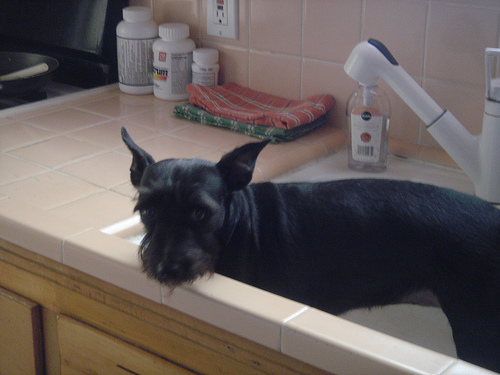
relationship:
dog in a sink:
[106, 113, 494, 374] [108, 28, 500, 374]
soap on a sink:
[339, 76, 396, 179] [108, 28, 500, 374]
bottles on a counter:
[109, 2, 224, 101] [2, 70, 302, 218]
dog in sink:
[106, 113, 494, 374] [108, 28, 500, 374]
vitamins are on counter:
[109, 2, 224, 101] [2, 70, 302, 218]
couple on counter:
[173, 82, 336, 144] [2, 70, 302, 218]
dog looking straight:
[106, 113, 494, 374] [131, 196, 215, 227]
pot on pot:
[3, 46, 66, 104] [0, 50, 59, 98]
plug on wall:
[202, 1, 242, 43] [168, 2, 463, 104]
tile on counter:
[7, 90, 189, 186] [2, 70, 302, 218]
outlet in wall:
[202, 1, 242, 43] [168, 2, 463, 104]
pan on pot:
[3, 46, 66, 104] [0, 50, 59, 98]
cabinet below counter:
[54, 312, 253, 374] [2, 70, 302, 218]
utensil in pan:
[2, 57, 52, 82] [3, 46, 66, 104]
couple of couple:
[174, 86, 323, 125] [173, 82, 336, 144]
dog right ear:
[117, 126, 500, 374] [210, 130, 272, 195]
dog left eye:
[117, 126, 500, 374] [137, 202, 164, 224]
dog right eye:
[117, 126, 500, 374] [185, 204, 211, 226]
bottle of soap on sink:
[339, 76, 396, 179] [284, 77, 460, 168]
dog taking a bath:
[106, 113, 494, 374] [166, 232, 494, 339]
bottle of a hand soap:
[339, 76, 396, 179] [327, 92, 423, 172]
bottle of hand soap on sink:
[331, 89, 411, 185] [302, 240, 426, 375]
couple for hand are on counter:
[173, 82, 336, 144] [77, 103, 134, 196]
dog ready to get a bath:
[106, 113, 494, 374] [267, 303, 454, 353]